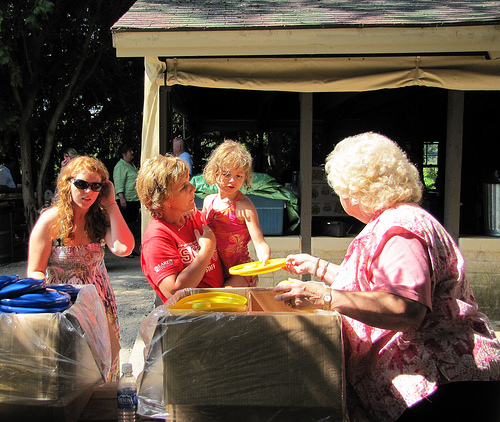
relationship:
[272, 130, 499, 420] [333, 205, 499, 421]
woman wearing a pink shirt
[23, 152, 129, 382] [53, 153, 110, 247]
girl with red hair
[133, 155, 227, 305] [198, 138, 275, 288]
woman carrying a child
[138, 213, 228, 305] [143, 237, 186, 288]
shirt has short sleeves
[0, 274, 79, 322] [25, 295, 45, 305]
frisbees in box are blue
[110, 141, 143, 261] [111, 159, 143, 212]
woman wearing green shirt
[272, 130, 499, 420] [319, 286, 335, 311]
woman wearing a watch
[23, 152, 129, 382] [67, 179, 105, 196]
girl wearing sunglasses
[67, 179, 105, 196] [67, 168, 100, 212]
sunglasses are on face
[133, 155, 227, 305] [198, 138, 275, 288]
woman holding child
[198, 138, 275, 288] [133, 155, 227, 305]
child in arms of woman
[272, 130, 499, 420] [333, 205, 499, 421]
woman wearing shirt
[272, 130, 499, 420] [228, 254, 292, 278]
woman holding frisbee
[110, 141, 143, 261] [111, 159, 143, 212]
woman wearing a green shirt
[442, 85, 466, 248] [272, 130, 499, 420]
post behind woman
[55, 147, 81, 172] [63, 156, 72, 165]
woman talking on phone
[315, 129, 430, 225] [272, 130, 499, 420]
head of a woman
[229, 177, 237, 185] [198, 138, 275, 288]
nose on child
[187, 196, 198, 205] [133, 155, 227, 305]
mouth on woman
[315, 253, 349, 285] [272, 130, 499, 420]
right arm of woman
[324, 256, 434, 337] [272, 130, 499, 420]
left arm of woman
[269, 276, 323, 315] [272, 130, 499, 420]
left hand on woman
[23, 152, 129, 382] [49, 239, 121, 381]
girl wearing a dress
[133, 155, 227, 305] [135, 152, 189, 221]
woman has hair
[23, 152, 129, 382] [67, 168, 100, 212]
girl has hand near face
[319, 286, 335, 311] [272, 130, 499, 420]
watch on wrist of woman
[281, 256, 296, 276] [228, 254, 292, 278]
fingers are on edge of frisbee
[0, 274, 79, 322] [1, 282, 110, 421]
frisbees are in a box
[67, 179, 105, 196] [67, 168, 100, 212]
sunglasses worn on face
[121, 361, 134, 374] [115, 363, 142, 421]
cap on water bottle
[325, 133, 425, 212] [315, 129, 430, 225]
curly white hair on head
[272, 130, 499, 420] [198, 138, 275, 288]
woman handing frisbee to child